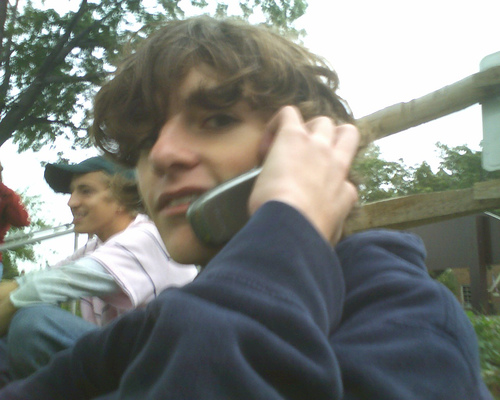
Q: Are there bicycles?
A: No, there are no bicycles.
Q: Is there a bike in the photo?
A: No, there are no bikes.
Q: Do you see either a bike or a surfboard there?
A: No, there are no bikes or surfboards.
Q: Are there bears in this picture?
A: No, there are no bears.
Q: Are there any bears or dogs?
A: No, there are no bears or dogs.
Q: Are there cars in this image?
A: No, there are no cars.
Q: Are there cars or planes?
A: No, there are no cars or planes.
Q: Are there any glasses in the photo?
A: No, there are no glasses.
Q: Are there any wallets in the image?
A: No, there are no wallets.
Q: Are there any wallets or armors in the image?
A: No, there are no wallets or armors.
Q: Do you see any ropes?
A: No, there are no ropes.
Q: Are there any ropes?
A: No, there are no ropes.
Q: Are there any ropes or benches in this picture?
A: No, there are no ropes or benches.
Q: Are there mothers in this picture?
A: No, there are no mothers.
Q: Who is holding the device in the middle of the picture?
A: The boy is holding the cell phone.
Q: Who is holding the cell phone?
A: The boy is holding the cell phone.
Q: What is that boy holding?
A: The boy is holding the cell phone.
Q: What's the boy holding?
A: The boy is holding the cell phone.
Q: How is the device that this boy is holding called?
A: The device is a cell phone.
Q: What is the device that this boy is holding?
A: The device is a cell phone.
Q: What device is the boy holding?
A: The boy is holding the mobile phone.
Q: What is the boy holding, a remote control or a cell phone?
A: The boy is holding a cell phone.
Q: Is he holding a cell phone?
A: Yes, the boy is holding a cell phone.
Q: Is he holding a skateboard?
A: No, the boy is holding a cell phone.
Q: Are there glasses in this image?
A: No, there are no glasses.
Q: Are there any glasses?
A: No, there are no glasses.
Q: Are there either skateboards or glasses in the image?
A: No, there are no glasses or skateboards.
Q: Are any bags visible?
A: No, there are no bags.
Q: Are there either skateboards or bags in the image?
A: No, there are no bags or skateboards.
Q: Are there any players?
A: No, there are no players.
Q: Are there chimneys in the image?
A: No, there are no chimneys.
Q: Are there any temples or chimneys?
A: No, there are no chimneys or temples.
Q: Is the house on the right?
A: Yes, the house is on the right of the image.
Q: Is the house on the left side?
A: No, the house is on the right of the image.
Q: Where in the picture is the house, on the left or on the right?
A: The house is on the right of the image.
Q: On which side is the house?
A: The house is on the right of the image.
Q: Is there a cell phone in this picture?
A: Yes, there is a cell phone.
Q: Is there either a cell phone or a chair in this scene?
A: Yes, there is a cell phone.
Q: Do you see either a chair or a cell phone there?
A: Yes, there is a cell phone.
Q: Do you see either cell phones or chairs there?
A: Yes, there is a cell phone.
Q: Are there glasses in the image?
A: No, there are no glasses.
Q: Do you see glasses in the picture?
A: No, there are no glasses.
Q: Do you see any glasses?
A: No, there are no glasses.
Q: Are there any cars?
A: No, there are no cars.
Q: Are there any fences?
A: Yes, there is a fence.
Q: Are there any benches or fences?
A: Yes, there is a fence.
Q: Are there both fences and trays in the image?
A: No, there is a fence but no trays.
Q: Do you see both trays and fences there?
A: No, there is a fence but no trays.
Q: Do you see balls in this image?
A: No, there are no balls.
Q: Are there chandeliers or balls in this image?
A: No, there are no balls or chandeliers.